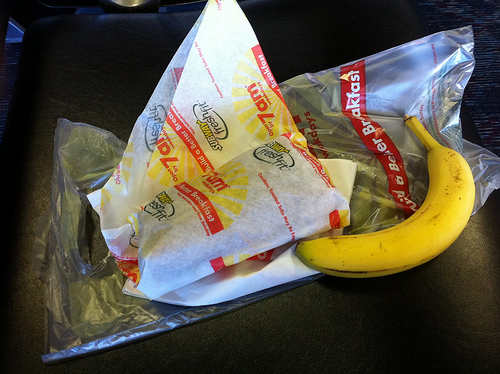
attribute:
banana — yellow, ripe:
[294, 114, 482, 280]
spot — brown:
[450, 161, 463, 188]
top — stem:
[403, 114, 445, 155]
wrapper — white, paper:
[102, 13, 339, 271]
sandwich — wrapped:
[144, 139, 306, 265]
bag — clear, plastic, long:
[33, 29, 498, 348]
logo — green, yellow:
[187, 99, 236, 151]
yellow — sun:
[178, 151, 207, 192]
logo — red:
[344, 68, 424, 215]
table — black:
[16, 17, 494, 366]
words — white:
[169, 118, 200, 155]